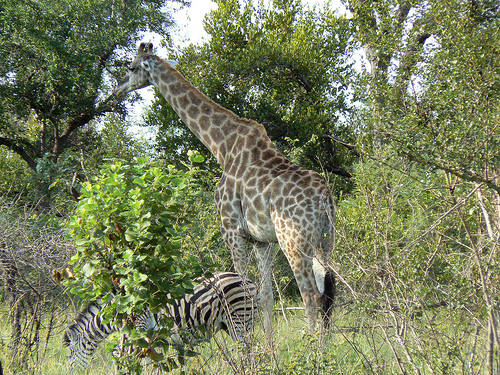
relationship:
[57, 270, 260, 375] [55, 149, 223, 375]
zebra behind bush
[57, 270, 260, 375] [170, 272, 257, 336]
zebra has stripes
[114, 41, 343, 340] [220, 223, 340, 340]
giraffe has legs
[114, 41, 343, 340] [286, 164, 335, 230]
giraffe has hind quarters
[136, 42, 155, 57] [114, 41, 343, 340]
horns on giraffe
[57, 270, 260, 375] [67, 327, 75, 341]
zebra has an ear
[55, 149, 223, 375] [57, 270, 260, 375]
bush in front of zebra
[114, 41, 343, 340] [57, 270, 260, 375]
giraffe near zebra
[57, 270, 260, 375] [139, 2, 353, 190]
zebra in front of tree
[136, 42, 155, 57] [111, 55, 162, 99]
horns on giraffes head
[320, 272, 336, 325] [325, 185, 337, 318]
dark hair at end of tail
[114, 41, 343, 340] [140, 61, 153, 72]
giraffe has an ear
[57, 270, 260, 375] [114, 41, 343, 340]
zebra near a giraffe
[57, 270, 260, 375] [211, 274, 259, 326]
zebra has a backside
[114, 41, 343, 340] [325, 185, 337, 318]
giraffe has a tail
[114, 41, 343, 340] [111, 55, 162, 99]
giraffe has a head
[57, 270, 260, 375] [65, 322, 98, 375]
zebra has a head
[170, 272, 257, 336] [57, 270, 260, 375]
stripes on top of zebra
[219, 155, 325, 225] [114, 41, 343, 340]
spots on giraffe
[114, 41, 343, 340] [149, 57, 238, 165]
giraffe with outstretched neck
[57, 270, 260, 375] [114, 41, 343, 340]
zebra and a giraffe